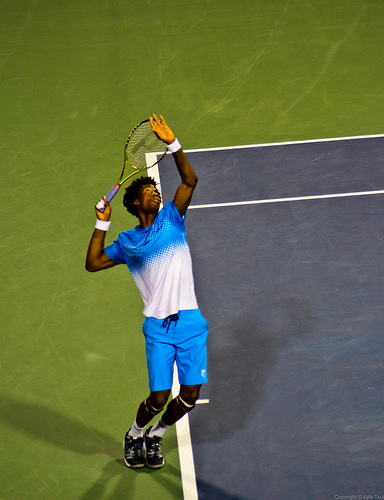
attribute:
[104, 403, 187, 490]
shoes — black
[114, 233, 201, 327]
shirt — white, blue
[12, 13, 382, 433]
court — clay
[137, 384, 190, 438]
sock — black, gold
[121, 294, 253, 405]
shorts — blue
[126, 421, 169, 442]
socks — white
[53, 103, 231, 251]
support band — white, black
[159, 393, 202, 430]
knee — black, white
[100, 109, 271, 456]
man — white, swinging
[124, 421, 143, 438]
sock — white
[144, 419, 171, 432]
sock — white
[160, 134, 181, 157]
band — white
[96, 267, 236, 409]
shorts — blue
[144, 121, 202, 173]
wrist band — white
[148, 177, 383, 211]
line — white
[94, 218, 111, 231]
band — white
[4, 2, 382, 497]
tennis court — green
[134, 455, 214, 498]
lines — white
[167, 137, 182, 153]
band — white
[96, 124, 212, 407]
person — looking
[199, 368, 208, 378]
symbol — white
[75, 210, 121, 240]
sweatband — white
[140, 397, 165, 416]
knee pads — black 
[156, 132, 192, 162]
band — white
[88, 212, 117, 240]
band — white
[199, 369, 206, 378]
logo — white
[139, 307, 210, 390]
shorts — blue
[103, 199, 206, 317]
shirt — white, blue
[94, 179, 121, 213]
handle — blue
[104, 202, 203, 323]
shirt — blue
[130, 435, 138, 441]
symbol — yellow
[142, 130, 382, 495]
tennis court — blue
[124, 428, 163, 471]
feet — together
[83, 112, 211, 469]
player — getting ready